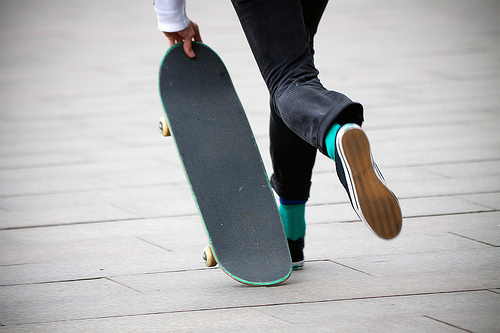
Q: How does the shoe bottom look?
A: Lifted up.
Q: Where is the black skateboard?
A: In the person's hand.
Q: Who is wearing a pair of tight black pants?
A: The person.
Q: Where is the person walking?
A: Light gray sidewalk.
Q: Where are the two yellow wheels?
A: On the skateboard.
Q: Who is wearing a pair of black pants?
A: The person.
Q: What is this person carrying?
A: Skateboard.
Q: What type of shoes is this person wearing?
A: Tennis shoes.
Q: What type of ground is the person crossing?
A: Concrete block.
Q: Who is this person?
A: A skateboarder.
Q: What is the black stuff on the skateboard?
A: Non-skid.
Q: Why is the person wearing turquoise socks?
A: They match the skateboard.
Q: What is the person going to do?
A: Ride the skateboard.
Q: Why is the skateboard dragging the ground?
A: Because it's heavy.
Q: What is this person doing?
A: Skateboarding.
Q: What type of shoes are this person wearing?
A: Tennis shoes.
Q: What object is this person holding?
A: A skateboard.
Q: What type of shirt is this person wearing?
A: A long sleeve shirt.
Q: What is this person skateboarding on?
A: Gray cement tiles.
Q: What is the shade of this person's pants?
A: Black.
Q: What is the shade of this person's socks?
A: Arctic Blue.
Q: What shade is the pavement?
A: Gray.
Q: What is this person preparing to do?
A: Jump on the skateboard.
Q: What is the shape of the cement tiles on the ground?
A: Rectangle.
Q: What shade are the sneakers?
A: Black.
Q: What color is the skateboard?
A: Black.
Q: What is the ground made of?
A: Concrete.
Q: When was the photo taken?
A: Daytime.